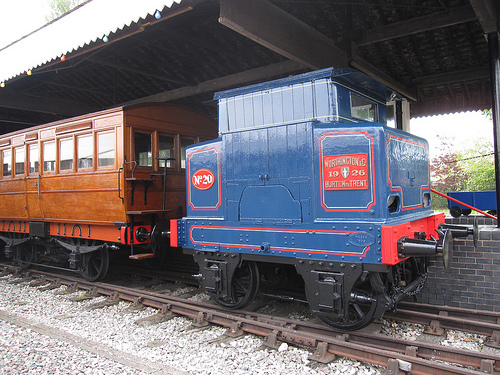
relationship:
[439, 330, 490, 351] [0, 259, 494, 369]
gravel between tracks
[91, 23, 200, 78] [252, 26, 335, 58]
roof supported beams